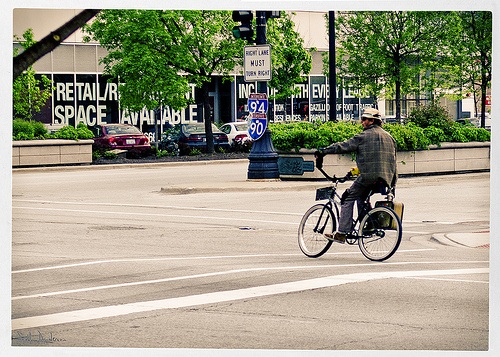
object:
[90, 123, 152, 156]
car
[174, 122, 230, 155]
car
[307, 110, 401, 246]
man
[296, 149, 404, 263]
bike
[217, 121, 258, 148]
car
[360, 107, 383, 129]
head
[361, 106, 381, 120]
hat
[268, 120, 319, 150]
plant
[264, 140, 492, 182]
median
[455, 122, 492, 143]
plant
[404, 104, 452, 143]
plant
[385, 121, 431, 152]
plant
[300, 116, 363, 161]
plant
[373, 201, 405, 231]
briefcase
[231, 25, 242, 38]
light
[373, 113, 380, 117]
feather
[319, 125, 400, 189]
jacket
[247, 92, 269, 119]
sign